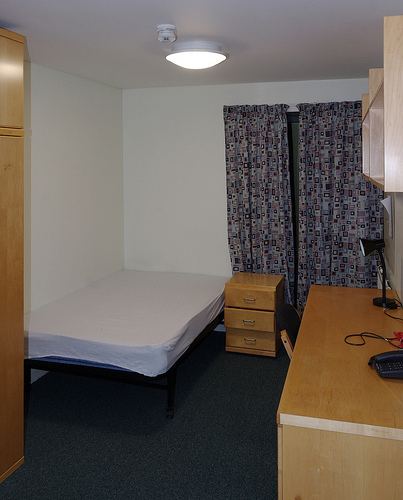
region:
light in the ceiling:
[159, 34, 239, 79]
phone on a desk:
[360, 345, 400, 382]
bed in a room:
[95, 296, 168, 400]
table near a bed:
[216, 270, 279, 354]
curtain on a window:
[214, 103, 360, 217]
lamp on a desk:
[345, 227, 395, 313]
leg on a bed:
[151, 384, 188, 419]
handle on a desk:
[233, 293, 262, 305]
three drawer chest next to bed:
[219, 262, 281, 367]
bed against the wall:
[26, 225, 219, 399]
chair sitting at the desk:
[267, 299, 311, 370]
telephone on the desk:
[362, 342, 401, 387]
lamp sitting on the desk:
[350, 225, 397, 320]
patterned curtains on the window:
[218, 97, 360, 266]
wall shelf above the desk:
[341, 14, 398, 202]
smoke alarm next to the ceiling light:
[148, 31, 183, 47]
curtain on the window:
[224, 102, 363, 270]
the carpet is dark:
[103, 405, 217, 459]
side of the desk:
[305, 430, 390, 476]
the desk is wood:
[314, 375, 338, 409]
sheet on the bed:
[88, 284, 162, 346]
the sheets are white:
[106, 277, 165, 329]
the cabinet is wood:
[216, 267, 277, 349]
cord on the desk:
[332, 318, 388, 345]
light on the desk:
[359, 231, 396, 310]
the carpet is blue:
[159, 449, 213, 486]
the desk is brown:
[303, 375, 346, 404]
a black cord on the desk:
[346, 325, 364, 346]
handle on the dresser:
[239, 313, 259, 327]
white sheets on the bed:
[98, 285, 169, 321]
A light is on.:
[160, 33, 230, 73]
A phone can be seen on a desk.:
[365, 347, 402, 384]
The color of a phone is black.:
[364, 347, 401, 386]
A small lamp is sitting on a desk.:
[350, 233, 402, 313]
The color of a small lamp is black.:
[355, 233, 402, 314]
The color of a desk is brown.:
[272, 280, 401, 499]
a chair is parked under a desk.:
[270, 298, 305, 361]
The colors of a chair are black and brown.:
[268, 297, 303, 364]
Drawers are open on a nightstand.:
[220, 265, 289, 361]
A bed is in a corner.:
[7, 265, 241, 427]